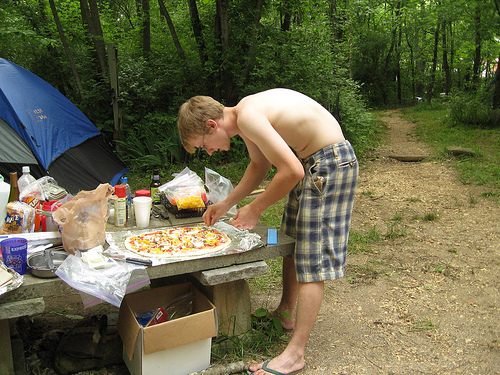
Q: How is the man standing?
A: Bent over.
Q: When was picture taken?
A: Daytime.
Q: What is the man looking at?
A: Pizza.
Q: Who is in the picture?
A: A man.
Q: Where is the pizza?
A: On pan.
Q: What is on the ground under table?
A: Box.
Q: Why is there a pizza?
A: To eat.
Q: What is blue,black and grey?
A: Tent.